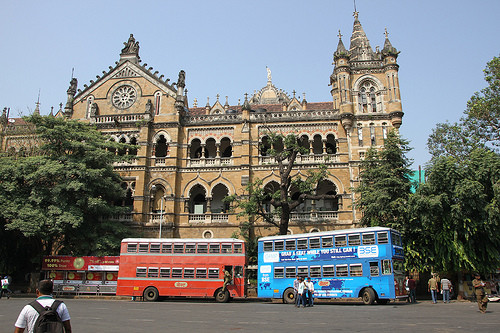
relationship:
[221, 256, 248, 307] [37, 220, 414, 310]
door of buses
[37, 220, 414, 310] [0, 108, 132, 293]
buses parked by tree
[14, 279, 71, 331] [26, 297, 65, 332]
man wearing backpack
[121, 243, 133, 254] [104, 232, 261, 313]
window on bus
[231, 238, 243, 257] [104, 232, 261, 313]
window on bus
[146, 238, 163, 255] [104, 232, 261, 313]
window on bus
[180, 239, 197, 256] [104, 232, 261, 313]
window on bus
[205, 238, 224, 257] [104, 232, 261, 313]
window on bus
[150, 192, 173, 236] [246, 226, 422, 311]
post next to bus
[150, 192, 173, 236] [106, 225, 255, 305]
post next to bus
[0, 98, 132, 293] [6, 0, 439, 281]
tree front of building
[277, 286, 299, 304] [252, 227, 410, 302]
wheel of bus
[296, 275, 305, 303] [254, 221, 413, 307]
people standing near bus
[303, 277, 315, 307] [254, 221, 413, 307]
people standing near bus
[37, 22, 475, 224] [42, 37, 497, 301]
sky above building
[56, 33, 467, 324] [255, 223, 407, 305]
building behind bus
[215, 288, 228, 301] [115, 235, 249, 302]
wheel on bus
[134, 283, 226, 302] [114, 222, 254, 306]
wheels on bus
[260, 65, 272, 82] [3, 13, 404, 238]
statue on building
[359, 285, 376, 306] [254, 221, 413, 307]
tire on bus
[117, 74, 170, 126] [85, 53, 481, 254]
window of building